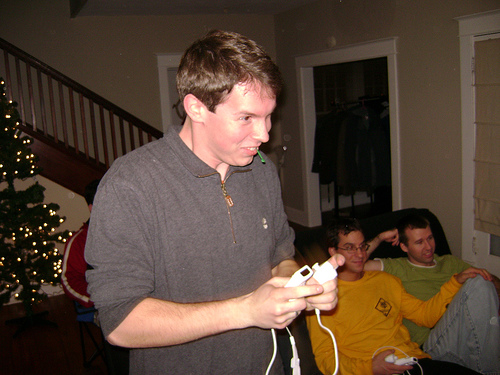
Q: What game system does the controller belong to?
A: Wii.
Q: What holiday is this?
A: Christmas.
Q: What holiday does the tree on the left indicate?
A: Christmas.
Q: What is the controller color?
A: White.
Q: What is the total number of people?
A: 4.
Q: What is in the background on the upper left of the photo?
A: Staircase.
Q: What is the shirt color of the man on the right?
A: Green.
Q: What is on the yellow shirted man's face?
A: Glasses.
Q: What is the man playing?
A: A video game.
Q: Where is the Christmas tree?
A: On the left by the stairs.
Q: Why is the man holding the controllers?
A: The man is playing a video game.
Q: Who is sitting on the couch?
A: Two men.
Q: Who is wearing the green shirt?
A: The man on the couch to the right.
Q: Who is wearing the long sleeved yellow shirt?
A: The man on the left on the couch.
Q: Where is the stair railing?
A: In the background near the Christmas tree.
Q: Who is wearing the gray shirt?
A: The man playing a video game.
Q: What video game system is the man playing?
A: A Wii.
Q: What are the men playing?
A: Video games.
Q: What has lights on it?
A: The Christmas tree.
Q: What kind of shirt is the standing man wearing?
A: A gray polo shirt.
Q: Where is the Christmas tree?
A: By the stairs.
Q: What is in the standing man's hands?
A: Video game controllers.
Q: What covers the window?
A: Blinds.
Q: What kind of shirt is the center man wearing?
A: A long sleeved yellow t-shirt.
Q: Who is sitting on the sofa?
A: 2 men.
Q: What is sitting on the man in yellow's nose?
A: Eyeglasses.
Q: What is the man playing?
A: Wii.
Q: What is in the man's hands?
A: Controllers.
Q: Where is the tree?
A: On the left.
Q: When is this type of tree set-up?
A: Around Christmas.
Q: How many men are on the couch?
A: 2.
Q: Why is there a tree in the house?
A: For Christmas.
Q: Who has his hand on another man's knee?
A: The man in yellow.